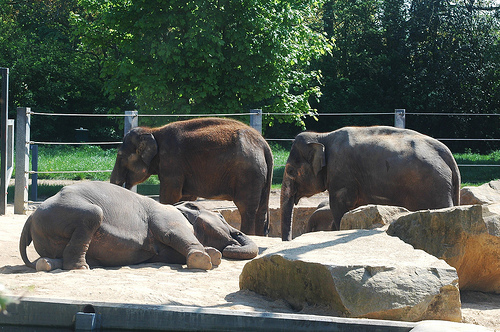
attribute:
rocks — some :
[238, 212, 454, 323]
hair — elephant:
[190, 115, 223, 142]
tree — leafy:
[120, 8, 321, 110]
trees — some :
[16, 9, 496, 144]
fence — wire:
[52, 107, 499, 139]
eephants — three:
[19, 115, 468, 265]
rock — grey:
[240, 210, 464, 324]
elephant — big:
[283, 127, 458, 206]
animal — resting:
[276, 125, 461, 240]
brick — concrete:
[6, 95, 40, 225]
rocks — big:
[256, 178, 457, 327]